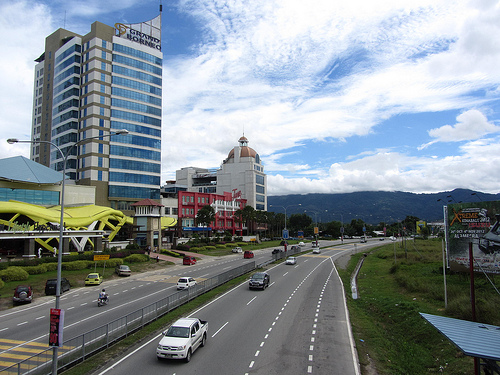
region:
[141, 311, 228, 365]
A white truck driving down the highway.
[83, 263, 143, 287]
Cars are parked on the side of the street.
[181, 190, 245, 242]
A red building off the highway.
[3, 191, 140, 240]
A building with a yellow roof.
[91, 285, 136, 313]
A person a motorcycle driving on the street.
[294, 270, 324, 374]
White lines in the middle of the street.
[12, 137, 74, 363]
The light pole is in the middle of the highway.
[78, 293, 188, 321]
The fence divides the highway.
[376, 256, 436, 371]
The grass is green.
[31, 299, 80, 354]
A red poster sign is attached to the pole.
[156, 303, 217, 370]
White truck on road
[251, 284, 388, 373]
White lines painted on road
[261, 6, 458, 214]
Blue sky with wispy clouds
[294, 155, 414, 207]
Large mountain overlooking city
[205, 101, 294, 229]
Tall tower with copper roof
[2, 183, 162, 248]
Yellow sloped roof on building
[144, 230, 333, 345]
Line of cars on road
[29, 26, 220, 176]
Tall building with windows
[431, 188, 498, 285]
Large billboard on side of road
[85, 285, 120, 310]
Person on a moped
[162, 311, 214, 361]
the pickup is white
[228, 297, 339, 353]
the roadd has three lanes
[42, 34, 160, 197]
the building has blue windows on the side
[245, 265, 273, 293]
the track is black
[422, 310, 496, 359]
the sheet is metallic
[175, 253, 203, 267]
the car is red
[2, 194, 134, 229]
the roofing is yellow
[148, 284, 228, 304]
there is a barricade on the raod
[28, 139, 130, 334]
the psot has two lights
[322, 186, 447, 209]
hills are in the background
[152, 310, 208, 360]
A white truck.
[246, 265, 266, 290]
A black car behind a white truck.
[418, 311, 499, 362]
A green roof on the right.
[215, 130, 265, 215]
A tall building with a rounded roof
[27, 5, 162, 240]
A very tall building with many windows.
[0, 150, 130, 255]
A building with a large yellow structure on it.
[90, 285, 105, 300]
A motorcycle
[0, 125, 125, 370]
A light pole on the left.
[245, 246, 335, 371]
A dotted line beside a dotted line in a road.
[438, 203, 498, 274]
A billboard on the right.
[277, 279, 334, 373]
The road is visible.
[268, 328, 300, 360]
The road is visible.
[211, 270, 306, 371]
The road is visible.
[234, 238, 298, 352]
The road is visible.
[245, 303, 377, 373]
The road is visible.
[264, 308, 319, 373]
The road is visible.